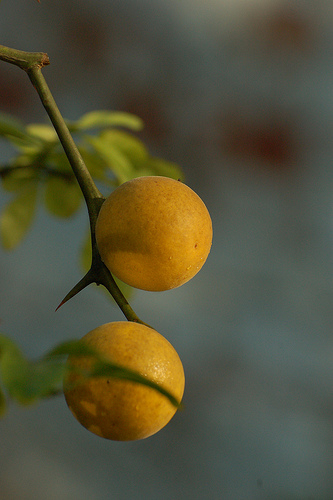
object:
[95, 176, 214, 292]
fruit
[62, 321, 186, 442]
fruit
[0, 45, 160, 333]
branch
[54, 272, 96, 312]
thorn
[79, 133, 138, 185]
leaf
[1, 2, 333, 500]
sky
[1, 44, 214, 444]
tree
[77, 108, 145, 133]
leaf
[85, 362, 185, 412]
leaf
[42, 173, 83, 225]
leaf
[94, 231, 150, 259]
shadow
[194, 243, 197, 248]
indentation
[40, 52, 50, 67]
break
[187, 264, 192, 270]
dew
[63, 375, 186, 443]
part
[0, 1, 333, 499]
distance